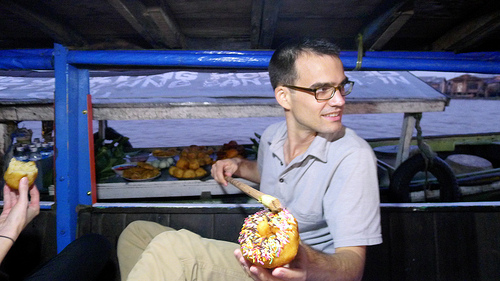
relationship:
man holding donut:
[109, 45, 384, 277] [236, 206, 298, 268]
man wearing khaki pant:
[109, 45, 384, 277] [122, 208, 258, 276]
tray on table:
[141, 150, 177, 172] [46, 145, 261, 201]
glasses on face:
[283, 80, 355, 100] [293, 54, 345, 132]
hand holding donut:
[233, 206, 315, 281] [232, 205, 299, 269]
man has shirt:
[109, 45, 384, 277] [236, 124, 412, 249]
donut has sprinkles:
[236, 200, 303, 265] [239, 208, 293, 265]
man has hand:
[109, 45, 384, 277] [224, 169, 278, 216]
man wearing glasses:
[109, 45, 384, 277] [280, 76, 352, 101]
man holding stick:
[109, 45, 384, 277] [228, 170, 278, 206]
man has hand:
[109, 45, 384, 277] [222, 227, 312, 278]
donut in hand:
[236, 200, 303, 265] [222, 227, 312, 278]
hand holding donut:
[230, 204, 316, 273] [235, 205, 294, 260]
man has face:
[109, 45, 384, 277] [306, 52, 347, 135]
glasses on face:
[283, 80, 354, 101] [306, 52, 347, 135]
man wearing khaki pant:
[109, 45, 384, 277] [118, 218, 257, 281]